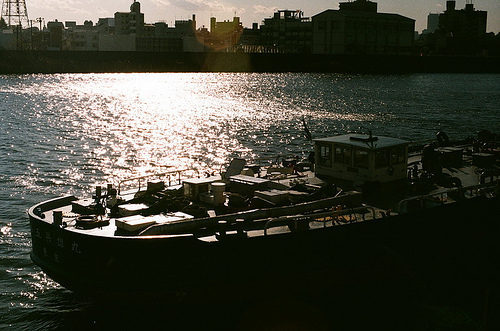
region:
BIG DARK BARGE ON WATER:
[23, 190, 490, 286]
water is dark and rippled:
[37, 153, 105, 179]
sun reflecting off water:
[85, 93, 185, 143]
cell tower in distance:
[4, 6, 46, 25]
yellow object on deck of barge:
[319, 208, 368, 237]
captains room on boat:
[314, 148, 389, 178]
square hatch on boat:
[119, 216, 161, 228]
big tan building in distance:
[307, 28, 398, 59]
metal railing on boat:
[249, 213, 385, 223]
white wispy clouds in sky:
[164, 7, 226, 26]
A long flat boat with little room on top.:
[27, 128, 499, 298]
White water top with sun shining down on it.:
[55, 70, 275, 143]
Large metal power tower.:
[0, 0, 31, 27]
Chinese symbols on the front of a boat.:
[31, 225, 83, 255]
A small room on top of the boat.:
[310, 131, 408, 183]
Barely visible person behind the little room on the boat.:
[421, 138, 439, 171]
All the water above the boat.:
[1, 71, 498, 131]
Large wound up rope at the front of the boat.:
[61, 213, 107, 230]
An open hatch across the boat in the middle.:
[222, 157, 246, 179]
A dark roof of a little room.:
[309, 132, 410, 150]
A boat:
[36, 116, 494, 291]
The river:
[13, 76, 460, 128]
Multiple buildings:
[4, 0, 493, 54]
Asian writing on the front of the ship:
[32, 224, 91, 266]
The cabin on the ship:
[316, 132, 407, 186]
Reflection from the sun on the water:
[38, 65, 275, 162]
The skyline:
[142, 0, 274, 17]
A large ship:
[35, 120, 496, 305]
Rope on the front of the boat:
[58, 205, 113, 231]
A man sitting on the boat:
[420, 135, 451, 179]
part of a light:
[173, 65, 230, 116]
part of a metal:
[236, 198, 261, 228]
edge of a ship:
[141, 225, 175, 254]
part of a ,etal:
[218, 215, 238, 247]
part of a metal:
[211, 174, 241, 232]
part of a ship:
[163, 208, 217, 280]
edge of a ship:
[172, 227, 239, 308]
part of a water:
[218, 148, 225, 159]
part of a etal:
[193, 205, 225, 230]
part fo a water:
[154, 124, 188, 177]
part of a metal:
[172, 202, 201, 239]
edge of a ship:
[210, 206, 237, 228]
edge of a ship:
[223, 212, 253, 244]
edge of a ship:
[182, 240, 223, 280]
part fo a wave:
[395, 88, 424, 99]